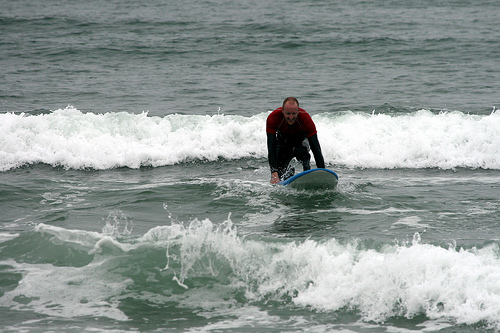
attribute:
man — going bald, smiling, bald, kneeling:
[264, 95, 327, 186]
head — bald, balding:
[279, 94, 302, 129]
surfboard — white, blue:
[281, 167, 341, 195]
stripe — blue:
[283, 167, 318, 181]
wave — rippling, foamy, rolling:
[32, 218, 499, 324]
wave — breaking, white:
[0, 107, 500, 177]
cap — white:
[173, 218, 217, 293]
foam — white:
[3, 257, 137, 327]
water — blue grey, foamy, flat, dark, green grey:
[1, 1, 500, 332]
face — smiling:
[283, 106, 300, 125]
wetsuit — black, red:
[263, 108, 327, 178]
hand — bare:
[267, 172, 285, 189]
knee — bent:
[296, 144, 312, 163]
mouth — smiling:
[285, 116, 296, 123]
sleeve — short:
[297, 110, 319, 141]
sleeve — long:
[307, 133, 328, 169]